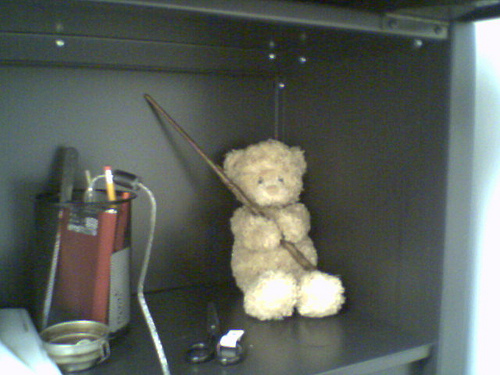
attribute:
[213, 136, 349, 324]
bear — small, brown, orange, light, close, looking, doll, sitting, yellow, fluffy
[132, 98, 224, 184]
stick — long, tall, skinny, brown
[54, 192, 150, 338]
glass — busy, sitting, full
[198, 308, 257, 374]
scissors — black, laying, close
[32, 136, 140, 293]
notebook — small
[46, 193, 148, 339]
cup — mesh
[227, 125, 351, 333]
bear — yellow fuzzy teddy